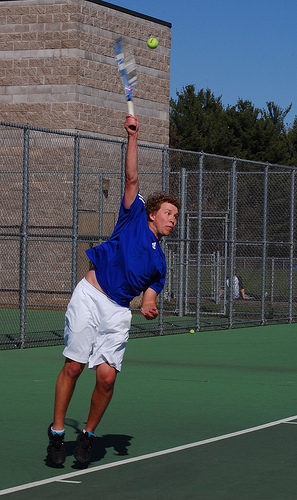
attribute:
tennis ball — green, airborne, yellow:
[146, 33, 160, 51]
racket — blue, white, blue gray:
[115, 36, 140, 134]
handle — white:
[127, 97, 136, 130]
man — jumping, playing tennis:
[44, 114, 181, 465]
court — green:
[1, 322, 294, 500]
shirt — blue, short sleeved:
[86, 186, 167, 308]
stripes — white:
[137, 190, 146, 206]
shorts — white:
[58, 275, 132, 371]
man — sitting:
[217, 268, 271, 301]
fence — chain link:
[0, 120, 296, 351]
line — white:
[1, 408, 296, 499]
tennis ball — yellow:
[187, 328, 197, 333]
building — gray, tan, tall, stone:
[0, 1, 170, 309]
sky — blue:
[103, 0, 297, 134]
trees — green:
[166, 83, 296, 256]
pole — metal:
[19, 127, 31, 350]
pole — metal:
[70, 132, 80, 297]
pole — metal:
[195, 150, 205, 333]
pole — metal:
[224, 155, 238, 329]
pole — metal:
[259, 161, 271, 324]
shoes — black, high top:
[44, 422, 95, 469]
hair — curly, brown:
[144, 190, 182, 215]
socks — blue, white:
[49, 424, 96, 438]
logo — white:
[150, 238, 157, 250]